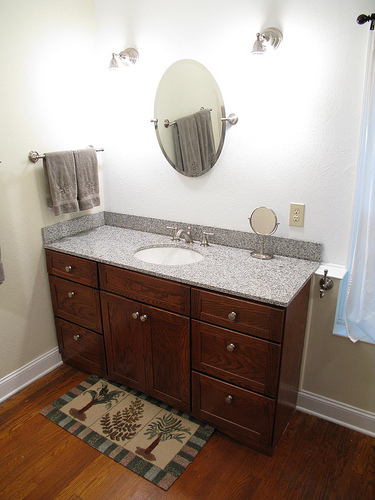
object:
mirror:
[248, 206, 280, 260]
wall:
[0, 0, 375, 440]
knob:
[65, 264, 72, 273]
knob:
[68, 290, 75, 298]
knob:
[73, 333, 80, 341]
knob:
[132, 311, 139, 320]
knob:
[140, 314, 147, 323]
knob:
[228, 311, 236, 320]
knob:
[227, 343, 235, 352]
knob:
[225, 395, 233, 405]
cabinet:
[42, 249, 313, 454]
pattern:
[59, 379, 201, 470]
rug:
[38, 372, 215, 492]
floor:
[0, 363, 374, 497]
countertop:
[41, 211, 322, 309]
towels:
[42, 150, 79, 216]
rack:
[28, 147, 106, 164]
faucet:
[174, 226, 194, 244]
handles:
[199, 231, 215, 247]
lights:
[109, 47, 140, 71]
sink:
[132, 245, 205, 266]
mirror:
[150, 57, 239, 177]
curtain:
[344, 29, 373, 344]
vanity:
[27, 25, 327, 456]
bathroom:
[0, 2, 375, 500]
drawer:
[188, 369, 276, 451]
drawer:
[189, 319, 283, 400]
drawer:
[190, 286, 286, 344]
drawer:
[56, 317, 108, 378]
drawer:
[50, 275, 103, 336]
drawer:
[45, 248, 100, 290]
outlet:
[289, 202, 305, 227]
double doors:
[98, 288, 191, 416]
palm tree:
[69, 381, 125, 421]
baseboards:
[0, 343, 63, 438]